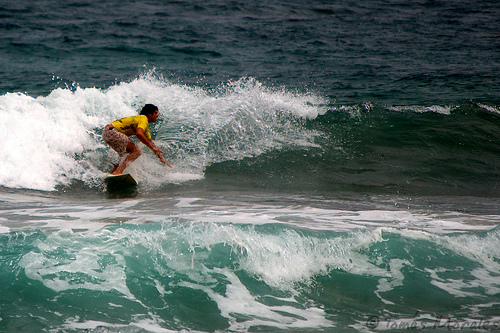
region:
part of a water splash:
[211, 101, 244, 161]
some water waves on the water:
[405, 100, 462, 170]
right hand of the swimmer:
[146, 145, 160, 158]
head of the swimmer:
[143, 93, 163, 126]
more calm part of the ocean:
[264, 14, 376, 76]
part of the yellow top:
[123, 122, 135, 131]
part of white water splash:
[6, 105, 53, 187]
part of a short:
[101, 125, 125, 155]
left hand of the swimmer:
[155, 154, 172, 164]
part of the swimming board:
[112, 168, 137, 204]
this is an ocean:
[193, 46, 471, 271]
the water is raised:
[5, 95, 65, 195]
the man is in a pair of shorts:
[100, 125, 125, 150]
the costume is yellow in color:
[110, 115, 142, 130]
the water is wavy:
[283, 38, 493, 85]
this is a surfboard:
[101, 171, 136, 187]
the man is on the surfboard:
[106, 114, 142, 176]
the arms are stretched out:
[138, 121, 167, 165]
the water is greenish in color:
[138, 260, 206, 324]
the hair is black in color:
[138, 102, 159, 114]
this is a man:
[104, 104, 174, 181]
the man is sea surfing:
[80, 101, 162, 208]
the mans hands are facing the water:
[142, 141, 170, 163]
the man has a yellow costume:
[116, 117, 146, 130]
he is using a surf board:
[106, 171, 132, 181]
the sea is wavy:
[166, 61, 276, 190]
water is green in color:
[5, 244, 437, 331]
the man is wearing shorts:
[106, 128, 126, 150]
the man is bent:
[92, 103, 162, 169]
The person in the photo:
[96, 98, 172, 193]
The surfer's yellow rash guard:
[109, 113, 155, 140]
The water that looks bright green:
[2, 228, 490, 332]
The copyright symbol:
[362, 308, 383, 332]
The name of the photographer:
[381, 310, 496, 331]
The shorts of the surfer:
[103, 123, 134, 155]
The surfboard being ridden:
[101, 169, 141, 198]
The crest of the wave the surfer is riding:
[2, 73, 324, 200]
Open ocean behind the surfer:
[2, 0, 494, 104]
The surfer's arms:
[136, 122, 178, 169]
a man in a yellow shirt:
[94, 103, 171, 194]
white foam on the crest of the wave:
[0, 62, 343, 198]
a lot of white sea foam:
[6, 193, 452, 255]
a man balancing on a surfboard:
[93, 98, 167, 195]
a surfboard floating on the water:
[96, 167, 146, 194]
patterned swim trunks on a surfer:
[95, 121, 133, 157]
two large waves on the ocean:
[3, 68, 498, 190]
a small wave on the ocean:
[15, 207, 498, 322]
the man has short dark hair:
[99, 98, 171, 191]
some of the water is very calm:
[0, 1, 495, 81]